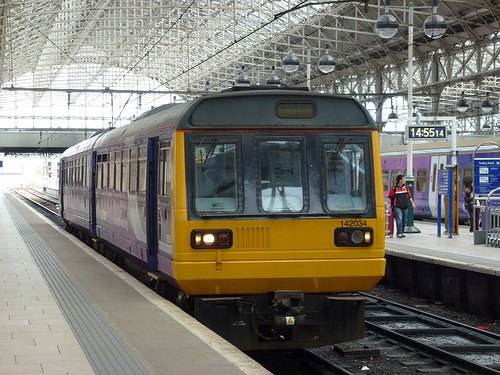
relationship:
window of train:
[194, 139, 239, 214] [57, 86, 387, 352]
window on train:
[258, 141, 305, 215] [57, 86, 387, 352]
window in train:
[323, 140, 367, 216] [57, 86, 387, 352]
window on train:
[194, 139, 239, 214] [57, 86, 387, 352]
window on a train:
[194, 139, 239, 214] [57, 86, 387, 352]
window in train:
[194, 139, 239, 214] [57, 86, 387, 352]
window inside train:
[194, 139, 239, 214] [57, 86, 387, 352]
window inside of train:
[194, 139, 239, 214] [57, 86, 387, 352]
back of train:
[61, 147, 67, 217] [57, 86, 387, 352]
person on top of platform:
[388, 174, 416, 237] [386, 214, 499, 325]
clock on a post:
[404, 114, 460, 238] [409, 123, 459, 236]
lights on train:
[189, 228, 374, 253] [57, 86, 387, 352]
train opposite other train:
[381, 145, 499, 224] [57, 86, 387, 352]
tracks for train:
[16, 185, 499, 371] [57, 86, 387, 352]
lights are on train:
[189, 228, 374, 253] [57, 86, 387, 352]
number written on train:
[338, 219, 367, 229] [57, 86, 387, 352]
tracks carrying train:
[16, 185, 499, 371] [57, 86, 387, 352]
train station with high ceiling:
[1, 1, 500, 374] [1, 2, 499, 137]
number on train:
[338, 219, 367, 229] [57, 86, 387, 352]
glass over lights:
[378, 27, 397, 38] [189, 228, 374, 253]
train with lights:
[57, 86, 387, 352] [189, 228, 374, 253]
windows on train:
[193, 134, 367, 217] [57, 86, 387, 352]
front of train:
[178, 94, 388, 300] [57, 86, 387, 352]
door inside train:
[148, 137, 160, 266] [57, 86, 387, 352]